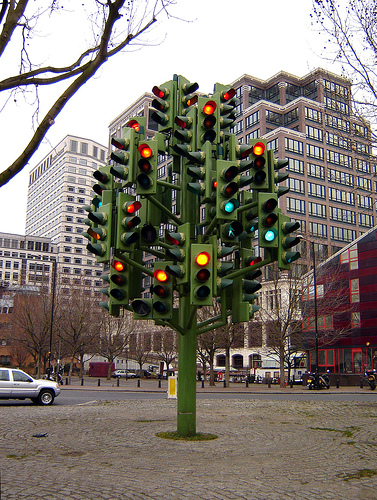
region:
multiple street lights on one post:
[79, 77, 315, 446]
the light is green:
[258, 222, 278, 247]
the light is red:
[191, 243, 219, 274]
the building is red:
[293, 225, 376, 381]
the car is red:
[85, 349, 122, 383]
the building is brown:
[216, 51, 372, 264]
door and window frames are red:
[317, 340, 366, 380]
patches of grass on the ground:
[295, 411, 375, 496]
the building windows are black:
[251, 77, 317, 138]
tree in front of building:
[249, 259, 358, 387]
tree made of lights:
[70, 118, 275, 351]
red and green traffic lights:
[99, 75, 275, 339]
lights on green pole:
[78, 71, 283, 425]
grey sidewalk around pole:
[77, 384, 157, 497]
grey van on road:
[5, 362, 97, 414]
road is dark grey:
[65, 380, 141, 403]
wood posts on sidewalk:
[81, 350, 144, 393]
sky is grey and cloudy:
[152, 7, 248, 60]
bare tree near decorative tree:
[1, 16, 178, 142]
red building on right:
[314, 265, 373, 398]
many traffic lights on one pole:
[77, 40, 302, 367]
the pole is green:
[145, 319, 245, 450]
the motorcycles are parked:
[270, 361, 375, 394]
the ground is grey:
[220, 392, 336, 488]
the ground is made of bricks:
[32, 413, 328, 481]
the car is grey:
[0, 355, 86, 414]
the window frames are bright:
[299, 337, 366, 389]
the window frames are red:
[293, 331, 366, 383]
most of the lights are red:
[98, 63, 289, 324]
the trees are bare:
[3, 299, 179, 393]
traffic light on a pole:
[187, 239, 216, 312]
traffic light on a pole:
[253, 188, 283, 255]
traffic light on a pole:
[143, 261, 174, 317]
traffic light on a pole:
[101, 247, 127, 306]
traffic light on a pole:
[114, 193, 143, 245]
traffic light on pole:
[115, 138, 157, 200]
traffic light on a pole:
[192, 87, 221, 152]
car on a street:
[10, 364, 74, 403]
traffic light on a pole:
[147, 82, 168, 130]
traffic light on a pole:
[276, 218, 306, 282]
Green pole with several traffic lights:
[79, 72, 303, 444]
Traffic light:
[187, 240, 216, 307]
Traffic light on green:
[256, 190, 280, 249]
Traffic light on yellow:
[187, 240, 216, 304]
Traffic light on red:
[115, 192, 139, 252]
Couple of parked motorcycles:
[305, 368, 331, 390]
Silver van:
[0, 366, 61, 404]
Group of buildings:
[0, 65, 376, 394]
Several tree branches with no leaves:
[2, 252, 359, 392]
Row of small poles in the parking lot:
[55, 374, 365, 395]